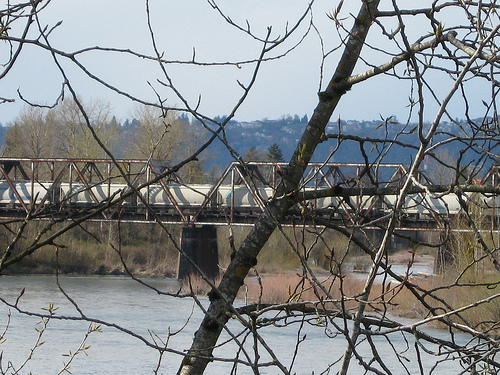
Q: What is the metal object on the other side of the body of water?
A: A guard rail.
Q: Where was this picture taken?
A: Near bridge.